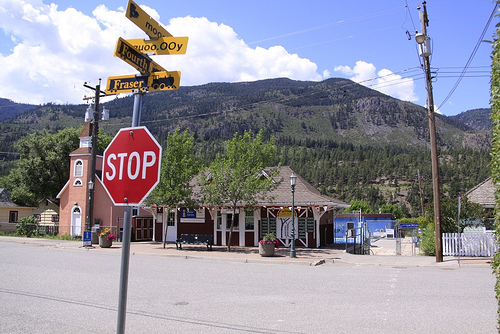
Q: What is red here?
A: Stop sign.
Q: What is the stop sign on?
A: Pole.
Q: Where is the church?
A: Next to the street.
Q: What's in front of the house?
A: Trees.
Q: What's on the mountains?
A: Trees.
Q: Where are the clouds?
A: Sky.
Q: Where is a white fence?
A: On the right.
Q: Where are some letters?
A: The sign.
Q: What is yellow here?
A: The signs.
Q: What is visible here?
A: The signs.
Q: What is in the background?
A: A mountain.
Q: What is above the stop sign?
A: Street signs.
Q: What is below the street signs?
A: A stop sign.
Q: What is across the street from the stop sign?
A: A small building.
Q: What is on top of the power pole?
A: A transformer.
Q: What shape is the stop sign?
A: Octagonal.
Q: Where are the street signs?
A: Above the stop sign.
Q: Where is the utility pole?
A: On the side of the street.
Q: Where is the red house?
A: Next to the road.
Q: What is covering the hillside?
A: Trees and grass.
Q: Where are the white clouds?
A: In the sky.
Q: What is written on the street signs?
A: Names and numbers of streets.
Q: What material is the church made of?
A: Bricks.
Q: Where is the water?
A: Behind the church.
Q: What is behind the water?
A: A large hillside.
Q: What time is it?
A: Afternoon.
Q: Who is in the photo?
A: No one.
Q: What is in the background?
A: Trees.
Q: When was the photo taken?
A: Daytime.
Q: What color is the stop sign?
A: Red.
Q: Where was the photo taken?
A: Along a street.